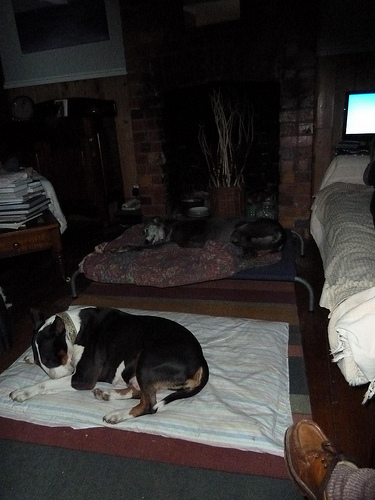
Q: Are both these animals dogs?
A: Yes, all the animals are dogs.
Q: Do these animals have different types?
A: No, all the animals are dogs.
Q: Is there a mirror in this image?
A: No, there are no mirrors.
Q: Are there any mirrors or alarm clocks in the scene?
A: No, there are no mirrors or alarm clocks.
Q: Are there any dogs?
A: Yes, there is a dog.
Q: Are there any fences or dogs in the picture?
A: Yes, there is a dog.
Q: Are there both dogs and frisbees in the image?
A: No, there is a dog but no frisbees.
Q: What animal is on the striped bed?
A: The dog is on the bed.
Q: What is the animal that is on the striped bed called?
A: The animal is a dog.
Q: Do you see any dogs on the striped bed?
A: Yes, there is a dog on the bed.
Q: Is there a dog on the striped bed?
A: Yes, there is a dog on the bed.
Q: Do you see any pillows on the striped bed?
A: No, there is a dog on the bed.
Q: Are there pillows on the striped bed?
A: No, there is a dog on the bed.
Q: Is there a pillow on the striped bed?
A: No, there is a dog on the bed.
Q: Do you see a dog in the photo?
A: Yes, there is a dog.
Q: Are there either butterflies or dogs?
A: Yes, there is a dog.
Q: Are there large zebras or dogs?
A: Yes, there is a large dog.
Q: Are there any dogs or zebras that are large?
A: Yes, the dog is large.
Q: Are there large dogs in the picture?
A: Yes, there is a large dog.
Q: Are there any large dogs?
A: Yes, there is a large dog.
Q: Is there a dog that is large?
A: Yes, there is a dog that is large.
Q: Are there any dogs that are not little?
A: Yes, there is a large dog.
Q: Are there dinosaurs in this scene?
A: No, there are no dinosaurs.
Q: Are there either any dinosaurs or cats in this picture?
A: No, there are no dinosaurs or cats.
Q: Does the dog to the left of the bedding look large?
A: Yes, the dog is large.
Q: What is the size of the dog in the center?
A: The dog is large.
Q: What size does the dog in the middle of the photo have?
A: The dog has large size.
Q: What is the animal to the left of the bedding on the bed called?
A: The animal is a dog.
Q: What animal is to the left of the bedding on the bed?
A: The animal is a dog.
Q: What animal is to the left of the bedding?
A: The animal is a dog.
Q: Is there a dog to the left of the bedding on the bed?
A: Yes, there is a dog to the left of the bedding.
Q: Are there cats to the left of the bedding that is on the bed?
A: No, there is a dog to the left of the bedding.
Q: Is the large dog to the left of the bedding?
A: Yes, the dog is to the left of the bedding.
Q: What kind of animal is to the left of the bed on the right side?
A: The animal is a dog.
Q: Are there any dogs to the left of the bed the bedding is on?
A: Yes, there is a dog to the left of the bed.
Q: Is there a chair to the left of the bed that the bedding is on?
A: No, there is a dog to the left of the bed.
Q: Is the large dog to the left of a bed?
A: Yes, the dog is to the left of a bed.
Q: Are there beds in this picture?
A: Yes, there is a bed.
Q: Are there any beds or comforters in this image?
A: Yes, there is a bed.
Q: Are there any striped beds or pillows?
A: Yes, there is a striped bed.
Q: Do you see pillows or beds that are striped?
A: Yes, the bed is striped.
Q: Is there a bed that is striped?
A: Yes, there is a striped bed.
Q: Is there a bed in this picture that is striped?
A: Yes, there is a bed that is striped.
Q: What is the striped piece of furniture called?
A: The piece of furniture is a bed.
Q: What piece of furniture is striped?
A: The piece of furniture is a bed.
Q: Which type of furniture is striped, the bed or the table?
A: The bed is striped.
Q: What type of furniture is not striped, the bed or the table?
A: The table is not striped.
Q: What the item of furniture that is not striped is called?
A: The piece of furniture is a table.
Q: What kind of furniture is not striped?
A: The furniture is a table.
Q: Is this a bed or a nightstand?
A: This is a bed.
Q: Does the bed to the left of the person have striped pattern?
A: Yes, the bed is striped.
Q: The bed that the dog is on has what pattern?
A: The bed is striped.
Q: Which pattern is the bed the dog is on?
A: The bed is striped.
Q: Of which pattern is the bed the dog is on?
A: The bed is striped.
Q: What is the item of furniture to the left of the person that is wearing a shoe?
A: The piece of furniture is a bed.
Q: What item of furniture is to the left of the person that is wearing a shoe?
A: The piece of furniture is a bed.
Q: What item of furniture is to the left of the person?
A: The piece of furniture is a bed.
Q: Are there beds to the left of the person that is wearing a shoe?
A: Yes, there is a bed to the left of the person.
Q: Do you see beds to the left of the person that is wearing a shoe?
A: Yes, there is a bed to the left of the person.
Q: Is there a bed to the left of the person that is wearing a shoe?
A: Yes, there is a bed to the left of the person.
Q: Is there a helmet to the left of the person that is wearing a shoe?
A: No, there is a bed to the left of the person.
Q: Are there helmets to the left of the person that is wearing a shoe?
A: No, there is a bed to the left of the person.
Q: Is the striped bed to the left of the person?
A: Yes, the bed is to the left of the person.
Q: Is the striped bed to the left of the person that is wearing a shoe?
A: Yes, the bed is to the left of the person.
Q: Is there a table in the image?
A: Yes, there is a table.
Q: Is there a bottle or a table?
A: Yes, there is a table.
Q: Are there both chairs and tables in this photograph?
A: No, there is a table but no chairs.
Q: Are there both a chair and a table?
A: No, there is a table but no chairs.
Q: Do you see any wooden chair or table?
A: Yes, there is a wood table.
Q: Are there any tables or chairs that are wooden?
A: Yes, the table is wooden.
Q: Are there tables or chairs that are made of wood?
A: Yes, the table is made of wood.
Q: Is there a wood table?
A: Yes, there is a table that is made of wood.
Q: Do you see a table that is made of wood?
A: Yes, there is a table that is made of wood.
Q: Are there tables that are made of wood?
A: Yes, there is a table that is made of wood.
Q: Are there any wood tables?
A: Yes, there is a table that is made of wood.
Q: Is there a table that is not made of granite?
A: Yes, there is a table that is made of wood.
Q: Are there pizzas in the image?
A: No, there are no pizzas.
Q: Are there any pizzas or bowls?
A: No, there are no pizzas or bowls.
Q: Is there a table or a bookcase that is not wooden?
A: No, there is a table but it is wooden.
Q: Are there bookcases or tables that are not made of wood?
A: No, there is a table but it is made of wood.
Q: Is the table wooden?
A: Yes, the table is wooden.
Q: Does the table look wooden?
A: Yes, the table is wooden.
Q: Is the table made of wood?
A: Yes, the table is made of wood.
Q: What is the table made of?
A: The table is made of wood.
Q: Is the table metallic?
A: No, the table is wooden.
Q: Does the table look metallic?
A: No, the table is wooden.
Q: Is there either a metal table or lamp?
A: No, there is a table but it is wooden.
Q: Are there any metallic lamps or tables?
A: No, there is a table but it is wooden.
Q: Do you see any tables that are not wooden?
A: No, there is a table but it is wooden.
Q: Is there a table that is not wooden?
A: No, there is a table but it is wooden.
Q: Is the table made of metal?
A: No, the table is made of wood.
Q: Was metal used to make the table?
A: No, the table is made of wood.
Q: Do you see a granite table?
A: No, there is a table but it is made of wood.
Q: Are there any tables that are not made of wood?
A: No, there is a table but it is made of wood.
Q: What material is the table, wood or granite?
A: The table is made of wood.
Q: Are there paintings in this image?
A: No, there are no paintings.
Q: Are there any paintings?
A: No, there are no paintings.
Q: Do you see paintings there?
A: No, there are no paintings.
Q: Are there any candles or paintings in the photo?
A: No, there are no paintings or candles.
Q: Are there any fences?
A: No, there are no fences.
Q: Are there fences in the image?
A: No, there are no fences.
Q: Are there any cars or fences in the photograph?
A: No, there are no fences or cars.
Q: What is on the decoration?
A: The tree is on the decoration.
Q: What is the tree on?
A: The tree is on the decoration.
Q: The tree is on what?
A: The tree is on the decoration.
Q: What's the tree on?
A: The tree is on the decoration.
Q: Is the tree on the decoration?
A: Yes, the tree is on the decoration.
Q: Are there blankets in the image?
A: Yes, there is a blanket.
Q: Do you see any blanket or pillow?
A: Yes, there is a blanket.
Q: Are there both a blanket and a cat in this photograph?
A: No, there is a blanket but no cats.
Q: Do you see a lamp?
A: No, there are no lamps.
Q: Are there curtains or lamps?
A: No, there are no lamps or curtains.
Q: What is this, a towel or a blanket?
A: This is a blanket.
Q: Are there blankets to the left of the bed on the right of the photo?
A: Yes, there is a blanket to the left of the bed.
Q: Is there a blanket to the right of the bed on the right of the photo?
A: No, the blanket is to the left of the bed.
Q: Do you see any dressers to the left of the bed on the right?
A: No, there is a blanket to the left of the bed.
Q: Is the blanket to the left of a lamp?
A: No, the blanket is to the left of a bed.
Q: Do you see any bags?
A: No, there are no bags.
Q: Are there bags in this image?
A: No, there are no bags.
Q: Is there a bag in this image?
A: No, there are no bags.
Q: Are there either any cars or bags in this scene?
A: No, there are no bags or cars.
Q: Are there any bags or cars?
A: No, there are no bags or cars.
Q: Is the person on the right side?
A: Yes, the person is on the right of the image.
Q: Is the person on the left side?
A: No, the person is on the right of the image.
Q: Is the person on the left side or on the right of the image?
A: The person is on the right of the image.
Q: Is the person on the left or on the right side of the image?
A: The person is on the right of the image.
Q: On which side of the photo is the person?
A: The person is on the right of the image.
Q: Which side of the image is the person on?
A: The person is on the right of the image.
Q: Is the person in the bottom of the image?
A: Yes, the person is in the bottom of the image.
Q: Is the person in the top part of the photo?
A: No, the person is in the bottom of the image.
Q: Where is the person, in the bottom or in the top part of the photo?
A: The person is in the bottom of the image.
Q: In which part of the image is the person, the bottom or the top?
A: The person is in the bottom of the image.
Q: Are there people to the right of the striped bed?
A: Yes, there is a person to the right of the bed.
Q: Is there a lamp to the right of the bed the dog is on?
A: No, there is a person to the right of the bed.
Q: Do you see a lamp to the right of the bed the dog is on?
A: No, there is a person to the right of the bed.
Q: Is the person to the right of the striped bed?
A: Yes, the person is to the right of the bed.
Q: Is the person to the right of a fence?
A: No, the person is to the right of the bed.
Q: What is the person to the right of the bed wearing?
A: The person is wearing a shoe.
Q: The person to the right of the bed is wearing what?
A: The person is wearing a shoe.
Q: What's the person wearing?
A: The person is wearing a shoe.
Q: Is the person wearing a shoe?
A: Yes, the person is wearing a shoe.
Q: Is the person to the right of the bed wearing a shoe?
A: Yes, the person is wearing a shoe.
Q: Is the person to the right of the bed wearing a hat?
A: No, the person is wearing a shoe.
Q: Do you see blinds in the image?
A: No, there are no blinds.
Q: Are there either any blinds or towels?
A: No, there are no blinds or towels.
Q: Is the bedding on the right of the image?
A: Yes, the bedding is on the right of the image.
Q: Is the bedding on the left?
A: No, the bedding is on the right of the image.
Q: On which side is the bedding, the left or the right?
A: The bedding is on the right of the image.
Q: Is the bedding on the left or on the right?
A: The bedding is on the right of the image.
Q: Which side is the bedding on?
A: The bedding is on the right of the image.